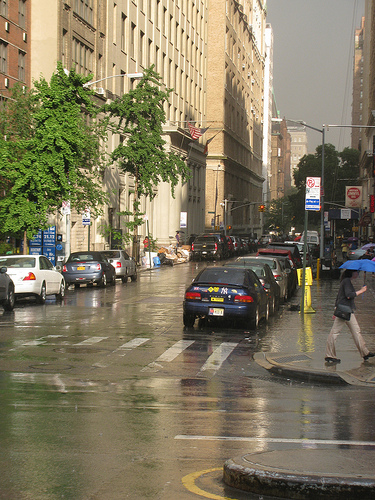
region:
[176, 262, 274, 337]
car parked on the street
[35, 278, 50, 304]
rear wheel on a vehicle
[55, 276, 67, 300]
front wheel on a vehicle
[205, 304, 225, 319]
rear licence plate on a vehicle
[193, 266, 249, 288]
rear windshield on a vehicle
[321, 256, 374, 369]
person with a blue umbrella walking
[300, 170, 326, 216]
sign on a pole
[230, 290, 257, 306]
rear tail light on a vehicle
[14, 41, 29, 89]
window on a building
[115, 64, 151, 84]
street light on a pole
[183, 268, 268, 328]
car parked on wet street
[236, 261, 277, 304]
car parked on wet street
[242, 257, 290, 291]
car parked on wet street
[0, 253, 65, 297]
car parked on wet street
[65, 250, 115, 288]
car parked on wet street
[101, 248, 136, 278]
car parked on wet street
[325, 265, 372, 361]
person walking on sidewalk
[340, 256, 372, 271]
blue umbrella of person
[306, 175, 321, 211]
white sign above car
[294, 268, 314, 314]
yellow sign by car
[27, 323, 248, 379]
white lines painted on wet pavement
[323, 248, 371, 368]
person walking on sidewalk with blue umbrella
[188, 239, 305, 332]
row of cars parked at the curb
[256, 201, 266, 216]
traffic light with red glowing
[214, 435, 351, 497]
raised cement median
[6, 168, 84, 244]
tree growing on the sidewalk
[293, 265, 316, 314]
yellow paper box on the sidewalk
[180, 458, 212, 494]
yellow line going around the median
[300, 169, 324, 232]
traffic signs on a pole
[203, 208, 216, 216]
street sign on a pole in the distance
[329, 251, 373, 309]
woman holding blue umbrella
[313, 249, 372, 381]
A woman walking on the sidewalk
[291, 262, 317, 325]
A yellow box on the sidewalk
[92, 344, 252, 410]
wet pavement after a rain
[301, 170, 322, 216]
A red and white sign on a pole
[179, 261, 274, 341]
A blue car parked on the street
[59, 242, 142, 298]
Two cars parked on the street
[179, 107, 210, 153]
An American flag on a building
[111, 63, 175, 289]
A tall tree on the side of a street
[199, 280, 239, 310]
Stickers on the back of a car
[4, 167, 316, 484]
City street with multiple cars parked on both sides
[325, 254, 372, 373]
Woman walking with blue umbrella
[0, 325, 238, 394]
White lines for pedestrian crossing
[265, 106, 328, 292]
Gray street light on pole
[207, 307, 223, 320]
Rear license plate on car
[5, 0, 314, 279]
Row of tall buildings all next to each other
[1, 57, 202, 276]
Green trees along sidewalk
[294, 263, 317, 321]
Yellow newspaper box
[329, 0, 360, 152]
Electric wires strung above city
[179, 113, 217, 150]
American flag hung on post on building